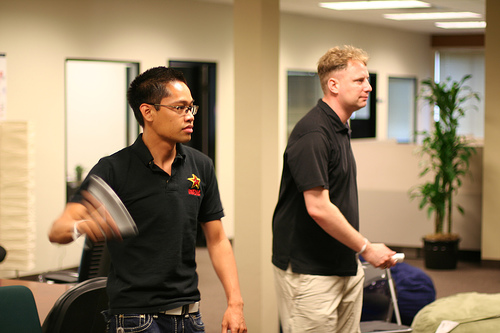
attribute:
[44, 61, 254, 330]
man — asian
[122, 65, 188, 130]
hair — black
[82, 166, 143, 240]
wii remote — white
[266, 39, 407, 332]
man — white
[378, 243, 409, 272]
wii remote — white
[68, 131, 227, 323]
shirt — black, polo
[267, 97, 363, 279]
shirt — black, polo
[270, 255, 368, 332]
pants — tan, white, khaki, wrinkled, brown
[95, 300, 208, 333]
jeans — blue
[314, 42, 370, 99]
hair — red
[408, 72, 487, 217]
leaves — green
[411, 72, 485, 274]
plant — tall, green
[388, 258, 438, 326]
luggage — purple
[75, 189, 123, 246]
hand — fast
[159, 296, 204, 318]
belt — white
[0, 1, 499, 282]
walls — painted, white